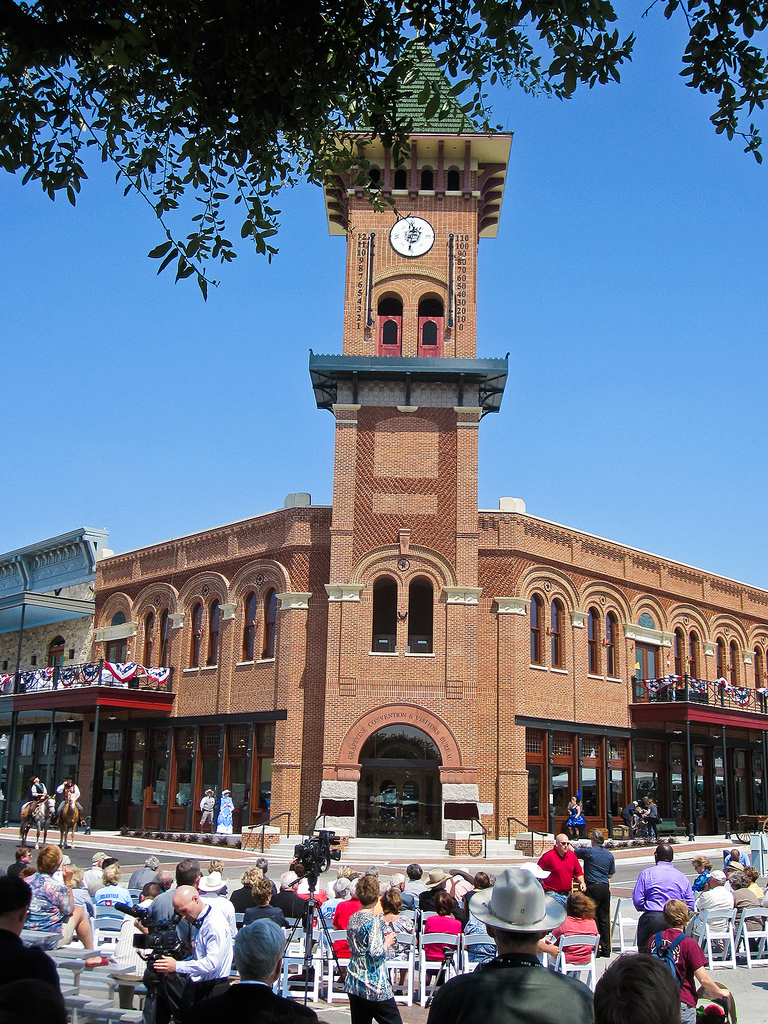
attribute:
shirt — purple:
[633, 858, 716, 926]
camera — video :
[287, 823, 342, 882]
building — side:
[366, 570, 415, 668]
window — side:
[259, 590, 280, 653]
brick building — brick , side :
[25, 39, 762, 834]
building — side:
[9, 506, 766, 835]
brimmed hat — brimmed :
[478, 869, 585, 944]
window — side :
[528, 589, 568, 673]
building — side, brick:
[68, 28, 765, 845]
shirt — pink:
[419, 914, 470, 972]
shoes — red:
[77, 945, 118, 971]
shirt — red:
[540, 846, 584, 893]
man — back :
[434, 855, 601, 1022]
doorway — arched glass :
[356, 727, 445, 848]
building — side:
[11, 59, 745, 832]